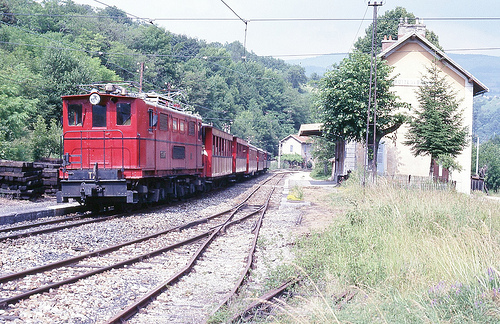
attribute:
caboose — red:
[48, 79, 212, 213]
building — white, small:
[280, 135, 334, 167]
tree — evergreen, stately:
[411, 70, 476, 181]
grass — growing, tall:
[290, 180, 492, 315]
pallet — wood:
[0, 152, 43, 199]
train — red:
[49, 67, 282, 212]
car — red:
[52, 80, 207, 212]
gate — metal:
[66, 131, 143, 178]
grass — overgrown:
[352, 186, 492, 311]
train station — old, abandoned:
[286, 122, 333, 177]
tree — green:
[413, 61, 465, 185]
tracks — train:
[173, 222, 305, 294]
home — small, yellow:
[265, 130, 321, 178]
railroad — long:
[192, 160, 281, 320]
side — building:
[390, 132, 413, 176]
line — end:
[57, 95, 208, 209]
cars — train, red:
[205, 120, 238, 176]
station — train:
[275, 117, 339, 196]